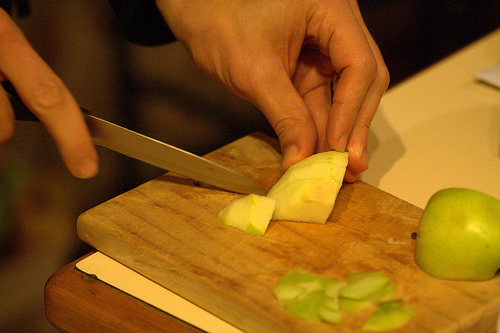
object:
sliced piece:
[217, 192, 278, 236]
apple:
[412, 186, 499, 280]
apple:
[219, 150, 347, 231]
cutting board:
[76, 131, 500, 332]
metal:
[88, 115, 267, 195]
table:
[42, 29, 499, 331]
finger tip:
[325, 125, 349, 150]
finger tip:
[346, 146, 365, 164]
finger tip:
[278, 142, 317, 172]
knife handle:
[0, 82, 91, 131]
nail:
[76, 155, 101, 178]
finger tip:
[59, 151, 102, 181]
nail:
[280, 144, 299, 161]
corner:
[43, 252, 242, 331]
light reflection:
[430, 200, 492, 269]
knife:
[1, 78, 265, 194]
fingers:
[280, 126, 369, 183]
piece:
[269, 151, 349, 223]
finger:
[324, 100, 350, 149]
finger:
[348, 124, 371, 159]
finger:
[249, 68, 317, 170]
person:
[0, 0, 392, 184]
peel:
[272, 268, 417, 331]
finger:
[16, 62, 101, 180]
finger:
[0, 86, 18, 145]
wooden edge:
[45, 265, 201, 332]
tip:
[210, 162, 269, 195]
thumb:
[257, 83, 319, 176]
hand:
[1, 8, 100, 180]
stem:
[409, 231, 420, 240]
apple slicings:
[217, 191, 274, 234]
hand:
[154, 1, 391, 183]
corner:
[421, 208, 500, 331]